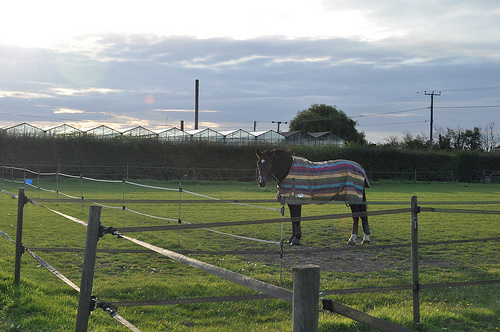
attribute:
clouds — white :
[71, 25, 428, 95]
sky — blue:
[2, 4, 499, 146]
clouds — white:
[79, 29, 337, 101]